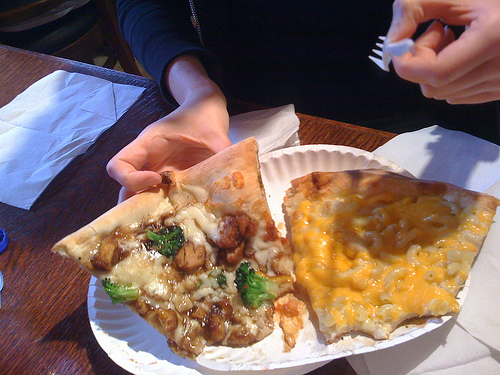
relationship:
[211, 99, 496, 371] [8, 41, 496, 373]
napkins on table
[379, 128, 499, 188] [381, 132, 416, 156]
napkins are on table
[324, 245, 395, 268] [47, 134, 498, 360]
sauce on pizza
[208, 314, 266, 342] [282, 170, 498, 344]
sauce on pizza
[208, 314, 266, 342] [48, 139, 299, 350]
sauce on pizza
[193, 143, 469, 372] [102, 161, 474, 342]
paper plate holding pizza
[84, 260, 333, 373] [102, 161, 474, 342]
paper plate holding pizza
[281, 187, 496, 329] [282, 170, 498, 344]
sauce on pizza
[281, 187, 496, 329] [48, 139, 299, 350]
sauce on pizza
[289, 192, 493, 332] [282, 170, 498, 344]
sauce on pizza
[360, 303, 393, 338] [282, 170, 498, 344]
sauce on pizza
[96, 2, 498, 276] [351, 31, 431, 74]
man holding fork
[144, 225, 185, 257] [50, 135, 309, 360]
broccoli on top of pizza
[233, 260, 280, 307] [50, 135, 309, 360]
broccoli on top of pizza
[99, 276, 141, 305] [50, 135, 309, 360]
broccoli on top of pizza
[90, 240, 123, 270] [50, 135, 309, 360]
chicken topping on pizza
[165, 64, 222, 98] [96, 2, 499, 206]
arm of man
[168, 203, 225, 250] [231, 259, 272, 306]
cheese and broccoli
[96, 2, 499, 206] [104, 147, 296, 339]
man holding pizza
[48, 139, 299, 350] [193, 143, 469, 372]
pizza on paper plate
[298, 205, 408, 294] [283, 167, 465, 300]
macaroni on pizza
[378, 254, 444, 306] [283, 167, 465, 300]
cheese on pizza